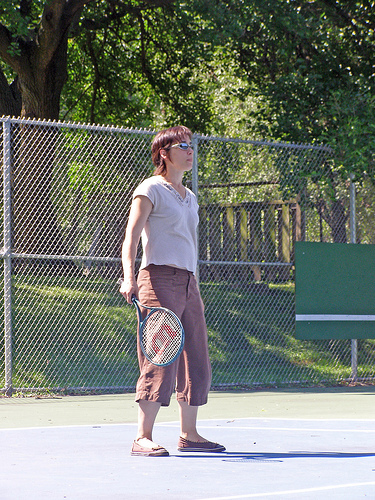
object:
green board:
[293, 238, 373, 343]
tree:
[0, 3, 83, 275]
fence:
[0, 114, 373, 392]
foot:
[176, 427, 226, 452]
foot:
[130, 431, 169, 457]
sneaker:
[176, 432, 227, 452]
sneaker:
[128, 438, 171, 457]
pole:
[352, 337, 358, 382]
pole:
[349, 178, 356, 246]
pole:
[4, 118, 14, 399]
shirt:
[130, 175, 199, 274]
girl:
[117, 125, 226, 458]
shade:
[241, 444, 298, 469]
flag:
[113, 119, 213, 282]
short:
[136, 265, 212, 407]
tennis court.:
[0, 0, 375, 500]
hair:
[148, 126, 192, 176]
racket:
[114, 275, 185, 366]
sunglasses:
[177, 143, 195, 150]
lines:
[250, 426, 369, 432]